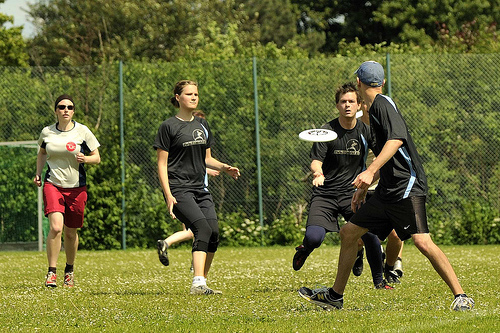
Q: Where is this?
A: This is at the field.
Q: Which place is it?
A: It is a field.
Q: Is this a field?
A: Yes, it is a field.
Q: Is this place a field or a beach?
A: It is a field.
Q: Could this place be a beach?
A: No, it is a field.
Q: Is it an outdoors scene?
A: Yes, it is outdoors.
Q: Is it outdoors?
A: Yes, it is outdoors.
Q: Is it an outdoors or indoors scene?
A: It is outdoors.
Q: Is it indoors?
A: No, it is outdoors.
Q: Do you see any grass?
A: Yes, there is grass.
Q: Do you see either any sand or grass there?
A: Yes, there is grass.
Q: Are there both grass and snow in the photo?
A: No, there is grass but no snow.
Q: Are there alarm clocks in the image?
A: No, there are no alarm clocks.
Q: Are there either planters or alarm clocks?
A: No, there are no alarm clocks or planters.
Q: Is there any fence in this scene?
A: Yes, there is a fence.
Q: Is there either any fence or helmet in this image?
A: Yes, there is a fence.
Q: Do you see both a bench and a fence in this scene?
A: No, there is a fence but no benches.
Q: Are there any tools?
A: No, there are no tools.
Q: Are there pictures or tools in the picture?
A: No, there are no tools or pictures.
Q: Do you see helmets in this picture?
A: No, there are no helmets.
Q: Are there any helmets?
A: No, there are no helmets.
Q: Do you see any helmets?
A: No, there are no helmets.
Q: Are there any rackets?
A: No, there are no rackets.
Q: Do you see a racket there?
A: No, there are no rackets.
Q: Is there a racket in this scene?
A: No, there are no rackets.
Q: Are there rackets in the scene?
A: No, there are no rackets.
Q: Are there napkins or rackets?
A: No, there are no rackets or napkins.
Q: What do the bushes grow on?
A: The bushes grow on the tree.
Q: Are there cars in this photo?
A: No, there are no cars.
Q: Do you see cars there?
A: No, there are no cars.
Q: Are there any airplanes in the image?
A: No, there are no airplanes.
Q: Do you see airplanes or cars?
A: No, there are no airplanes or cars.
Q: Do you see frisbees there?
A: Yes, there is a frisbee.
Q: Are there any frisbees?
A: Yes, there is a frisbee.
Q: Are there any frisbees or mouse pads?
A: Yes, there is a frisbee.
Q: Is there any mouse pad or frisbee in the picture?
A: Yes, there is a frisbee.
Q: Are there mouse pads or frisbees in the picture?
A: Yes, there is a frisbee.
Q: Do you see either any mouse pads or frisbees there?
A: Yes, there is a frisbee.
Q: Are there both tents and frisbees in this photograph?
A: No, there is a frisbee but no tents.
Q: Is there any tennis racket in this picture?
A: No, there are no rackets.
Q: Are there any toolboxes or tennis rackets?
A: No, there are no tennis rackets or toolboxes.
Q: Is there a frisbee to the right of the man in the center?
A: Yes, there is a frisbee to the right of the man.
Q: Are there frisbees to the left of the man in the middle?
A: No, the frisbee is to the right of the man.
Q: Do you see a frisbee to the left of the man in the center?
A: No, the frisbee is to the right of the man.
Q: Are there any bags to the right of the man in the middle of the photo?
A: No, there is a frisbee to the right of the man.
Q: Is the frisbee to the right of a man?
A: Yes, the frisbee is to the right of a man.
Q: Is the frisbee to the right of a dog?
A: No, the frisbee is to the right of a man.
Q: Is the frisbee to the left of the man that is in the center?
A: No, the frisbee is to the right of the man.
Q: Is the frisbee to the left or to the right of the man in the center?
A: The frisbee is to the right of the man.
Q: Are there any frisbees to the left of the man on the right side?
A: Yes, there is a frisbee to the left of the man.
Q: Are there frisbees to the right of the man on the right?
A: No, the frisbee is to the left of the man.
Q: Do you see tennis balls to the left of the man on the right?
A: No, there is a frisbee to the left of the man.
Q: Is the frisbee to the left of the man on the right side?
A: Yes, the frisbee is to the left of the man.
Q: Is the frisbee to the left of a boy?
A: No, the frisbee is to the left of the man.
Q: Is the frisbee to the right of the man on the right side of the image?
A: No, the frisbee is to the left of the man.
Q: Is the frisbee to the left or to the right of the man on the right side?
A: The frisbee is to the left of the man.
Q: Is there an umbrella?
A: No, there are no umbrellas.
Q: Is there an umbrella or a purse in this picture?
A: No, there are no umbrellas or purses.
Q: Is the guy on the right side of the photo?
A: Yes, the guy is on the right of the image.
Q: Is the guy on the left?
A: No, the guy is on the right of the image.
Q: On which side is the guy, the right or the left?
A: The guy is on the right of the image.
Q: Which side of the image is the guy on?
A: The guy is on the right of the image.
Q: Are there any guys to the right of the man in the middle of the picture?
A: Yes, there is a guy to the right of the man.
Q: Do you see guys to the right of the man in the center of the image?
A: Yes, there is a guy to the right of the man.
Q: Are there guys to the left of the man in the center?
A: No, the guy is to the right of the man.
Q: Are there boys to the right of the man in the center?
A: No, there is a guy to the right of the man.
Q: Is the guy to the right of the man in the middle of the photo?
A: Yes, the guy is to the right of the man.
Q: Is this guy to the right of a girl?
A: No, the guy is to the right of the man.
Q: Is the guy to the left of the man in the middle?
A: No, the guy is to the right of the man.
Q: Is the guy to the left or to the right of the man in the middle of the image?
A: The guy is to the right of the man.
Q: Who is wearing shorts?
A: The guy is wearing shorts.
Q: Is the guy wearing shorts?
A: Yes, the guy is wearing shorts.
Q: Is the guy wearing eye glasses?
A: No, the guy is wearing shorts.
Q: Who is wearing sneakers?
A: The guy is wearing sneakers.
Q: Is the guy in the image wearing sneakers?
A: Yes, the guy is wearing sneakers.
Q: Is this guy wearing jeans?
A: No, the guy is wearing sneakers.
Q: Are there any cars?
A: No, there are no cars.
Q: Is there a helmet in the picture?
A: No, there are no helmets.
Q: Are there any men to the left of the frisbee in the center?
A: Yes, there is a man to the left of the frisbee.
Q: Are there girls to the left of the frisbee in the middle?
A: No, there is a man to the left of the frisbee.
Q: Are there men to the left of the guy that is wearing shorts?
A: Yes, there is a man to the left of the guy.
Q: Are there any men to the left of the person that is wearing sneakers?
A: Yes, there is a man to the left of the guy.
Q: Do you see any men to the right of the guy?
A: No, the man is to the left of the guy.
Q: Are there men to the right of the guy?
A: No, the man is to the left of the guy.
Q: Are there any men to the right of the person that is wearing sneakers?
A: No, the man is to the left of the guy.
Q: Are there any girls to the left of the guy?
A: No, there is a man to the left of the guy.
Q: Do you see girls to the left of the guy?
A: No, there is a man to the left of the guy.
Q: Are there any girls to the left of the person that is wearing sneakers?
A: No, there is a man to the left of the guy.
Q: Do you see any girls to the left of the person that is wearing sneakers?
A: No, there is a man to the left of the guy.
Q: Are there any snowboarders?
A: No, there are no snowboarders.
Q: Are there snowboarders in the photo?
A: No, there are no snowboarders.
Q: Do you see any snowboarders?
A: No, there are no snowboarders.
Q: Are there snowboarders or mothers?
A: No, there are no snowboarders or mothers.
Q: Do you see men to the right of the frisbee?
A: Yes, there is a man to the right of the frisbee.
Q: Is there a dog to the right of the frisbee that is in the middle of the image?
A: No, there is a man to the right of the frisbee.